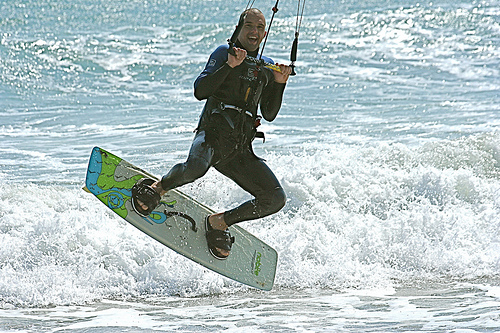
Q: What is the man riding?
A: A wakeboard.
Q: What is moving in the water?
A: Waves.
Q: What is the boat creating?
A: Waves.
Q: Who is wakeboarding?
A: A man.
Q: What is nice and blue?
A: Water.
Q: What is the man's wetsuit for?
A: So he doesn't get wet.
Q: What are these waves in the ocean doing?
A: Crashing.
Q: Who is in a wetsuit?
A: The man.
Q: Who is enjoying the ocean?
A: The man.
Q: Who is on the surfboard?
A: Man that is barefoot.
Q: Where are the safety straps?
A: Over wetsuit.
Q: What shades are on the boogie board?
A: White green and blue.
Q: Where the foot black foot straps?
A: On boogie board.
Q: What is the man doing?
A: Windsurfing.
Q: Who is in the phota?
A: A man.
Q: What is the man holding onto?
A: Handle to kite.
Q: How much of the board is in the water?
A: None of it.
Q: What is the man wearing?
A: Wetsuit.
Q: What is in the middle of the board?
A: Handle.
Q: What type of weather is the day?
A: Sunny.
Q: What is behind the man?
A: Wave.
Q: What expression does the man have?
A: Smiling.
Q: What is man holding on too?
A: Bar.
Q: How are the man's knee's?
A: Bent.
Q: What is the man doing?
A: Wakeboarding.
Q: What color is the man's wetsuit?
A: Black.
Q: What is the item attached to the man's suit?
A: A wakeboard.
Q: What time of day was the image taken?
A: Daytime.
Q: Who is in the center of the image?
A: A man.